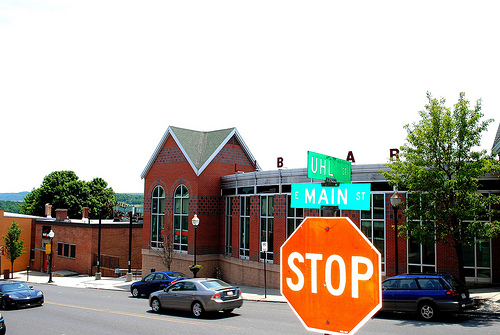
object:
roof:
[221, 161, 500, 190]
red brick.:
[199, 178, 220, 195]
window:
[173, 185, 189, 252]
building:
[0, 210, 34, 275]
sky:
[0, 0, 500, 195]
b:
[277, 157, 283, 168]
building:
[139, 125, 500, 291]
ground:
[0, 92, 500, 279]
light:
[191, 213, 199, 225]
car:
[129, 271, 189, 298]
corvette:
[0, 281, 45, 312]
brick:
[155, 162, 188, 177]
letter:
[349, 256, 372, 299]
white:
[352, 256, 358, 297]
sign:
[279, 216, 382, 335]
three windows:
[58, 242, 77, 259]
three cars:
[0, 270, 243, 319]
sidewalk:
[0, 268, 500, 317]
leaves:
[17, 171, 119, 219]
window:
[285, 195, 304, 242]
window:
[151, 186, 165, 248]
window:
[238, 195, 249, 260]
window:
[225, 196, 232, 254]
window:
[259, 195, 273, 262]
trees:
[19, 170, 118, 220]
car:
[373, 273, 475, 320]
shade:
[394, 296, 499, 329]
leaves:
[383, 93, 500, 242]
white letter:
[306, 253, 323, 293]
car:
[149, 278, 243, 316]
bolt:
[326, 228, 328, 230]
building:
[32, 203, 144, 277]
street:
[0, 277, 500, 335]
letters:
[285, 250, 306, 291]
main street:
[305, 188, 347, 205]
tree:
[377, 91, 499, 303]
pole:
[189, 225, 202, 278]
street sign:
[291, 182, 372, 210]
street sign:
[308, 151, 352, 184]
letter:
[346, 151, 355, 162]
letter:
[254, 160, 256, 169]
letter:
[235, 162, 238, 172]